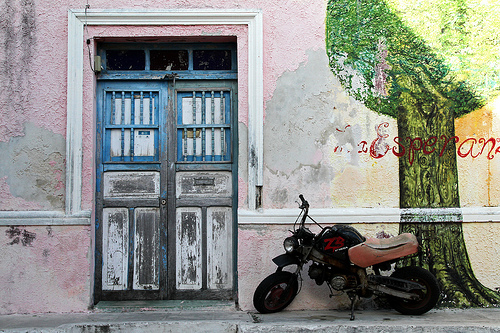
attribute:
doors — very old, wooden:
[94, 34, 236, 309]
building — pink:
[4, 12, 490, 253]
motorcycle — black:
[259, 196, 455, 331]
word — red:
[355, 118, 496, 160]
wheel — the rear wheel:
[385, 266, 440, 316]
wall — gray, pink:
[8, 2, 73, 222]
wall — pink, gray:
[256, 34, 343, 170]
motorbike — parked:
[245, 198, 440, 310]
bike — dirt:
[252, 195, 439, 315]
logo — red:
[317, 225, 369, 262]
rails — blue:
[78, 61, 253, 171]